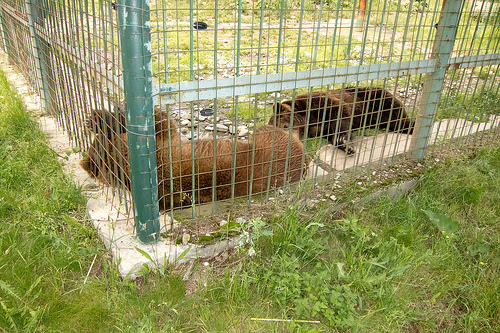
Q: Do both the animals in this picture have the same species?
A: No, they are dogs and bears.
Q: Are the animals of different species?
A: Yes, they are dogs and bears.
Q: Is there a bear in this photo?
A: Yes, there is a bear.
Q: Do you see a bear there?
A: Yes, there is a bear.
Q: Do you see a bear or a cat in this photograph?
A: Yes, there is a bear.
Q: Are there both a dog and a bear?
A: Yes, there are both a bear and a dog.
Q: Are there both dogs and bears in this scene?
A: Yes, there are both a bear and a dog.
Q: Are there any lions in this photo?
A: No, there are no lions.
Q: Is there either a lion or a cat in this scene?
A: No, there are no lions or cats.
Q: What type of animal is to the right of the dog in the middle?
A: The animal is a bear.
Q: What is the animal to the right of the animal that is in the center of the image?
A: The animal is a bear.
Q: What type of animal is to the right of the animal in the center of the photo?
A: The animal is a bear.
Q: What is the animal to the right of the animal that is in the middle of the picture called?
A: The animal is a bear.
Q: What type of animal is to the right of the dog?
A: The animal is a bear.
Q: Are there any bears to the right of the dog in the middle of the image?
A: Yes, there is a bear to the right of the dog.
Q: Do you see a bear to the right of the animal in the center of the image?
A: Yes, there is a bear to the right of the dog.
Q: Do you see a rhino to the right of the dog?
A: No, there is a bear to the right of the dog.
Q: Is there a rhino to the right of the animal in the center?
A: No, there is a bear to the right of the dog.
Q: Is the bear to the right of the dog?
A: Yes, the bear is to the right of the dog.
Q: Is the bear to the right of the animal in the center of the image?
A: Yes, the bear is to the right of the dog.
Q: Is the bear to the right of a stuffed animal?
A: No, the bear is to the right of the dog.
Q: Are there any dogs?
A: Yes, there is a dog.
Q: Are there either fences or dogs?
A: Yes, there is a dog.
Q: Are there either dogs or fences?
A: Yes, there is a dog.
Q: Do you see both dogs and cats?
A: No, there is a dog but no cats.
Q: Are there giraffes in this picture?
A: No, there are no giraffes.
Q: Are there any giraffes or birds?
A: No, there are no giraffes or birds.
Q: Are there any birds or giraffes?
A: No, there are no giraffes or birds.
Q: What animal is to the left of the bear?
A: The animal is a dog.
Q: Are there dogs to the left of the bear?
A: Yes, there is a dog to the left of the bear.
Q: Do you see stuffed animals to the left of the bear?
A: No, there is a dog to the left of the bear.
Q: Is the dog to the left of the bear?
A: Yes, the dog is to the left of the bear.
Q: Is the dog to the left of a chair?
A: No, the dog is to the left of the bear.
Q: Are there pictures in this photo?
A: No, there are no pictures.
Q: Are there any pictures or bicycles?
A: No, there are no pictures or bicycles.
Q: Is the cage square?
A: Yes, the cage is square.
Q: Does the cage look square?
A: Yes, the cage is square.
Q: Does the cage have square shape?
A: Yes, the cage is square.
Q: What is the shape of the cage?
A: The cage is square.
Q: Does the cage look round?
A: No, the cage is square.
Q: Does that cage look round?
A: No, the cage is square.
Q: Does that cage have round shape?
A: No, the cage is square.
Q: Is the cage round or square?
A: The cage is square.